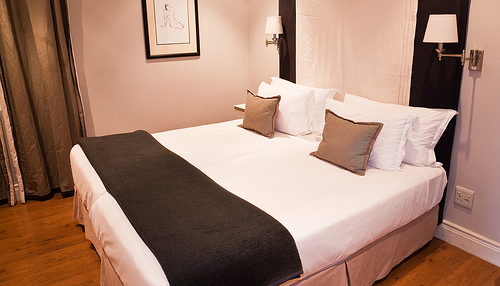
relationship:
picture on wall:
[140, 0, 199, 59] [85, 0, 137, 127]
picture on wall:
[140, 0, 199, 59] [88, 0, 140, 131]